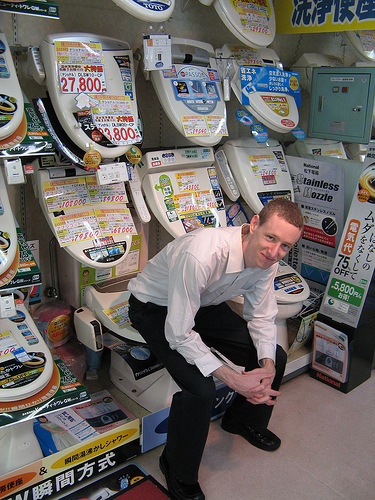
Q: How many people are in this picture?
A: One.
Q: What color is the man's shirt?
A: White.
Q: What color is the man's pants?
A: Black.